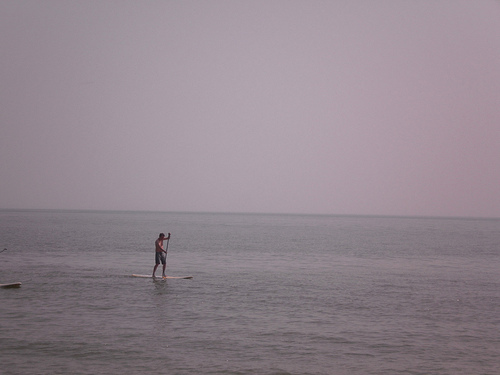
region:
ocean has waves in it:
[2, 191, 495, 373]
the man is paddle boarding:
[141, 226, 202, 296]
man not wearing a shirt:
[141, 223, 198, 293]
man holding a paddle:
[131, 211, 200, 293]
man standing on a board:
[128, 228, 195, 284]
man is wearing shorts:
[136, 242, 173, 275]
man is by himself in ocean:
[137, 220, 200, 289]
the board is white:
[122, 258, 209, 295]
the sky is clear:
[0, 1, 467, 219]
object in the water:
[2, 271, 27, 304]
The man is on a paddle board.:
[128, 228, 197, 285]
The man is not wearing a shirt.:
[131, 231, 196, 282]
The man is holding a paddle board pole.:
[133, 225, 193, 284]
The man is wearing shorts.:
[126, 227, 194, 293]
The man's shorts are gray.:
[131, 232, 193, 285]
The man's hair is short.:
[127, 230, 198, 285]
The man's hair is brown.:
[133, 233, 194, 285]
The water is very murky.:
[270, 317, 382, 368]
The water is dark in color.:
[301, 308, 375, 353]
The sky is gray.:
[316, 146, 400, 205]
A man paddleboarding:
[128, 223, 205, 292]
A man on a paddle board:
[122, 227, 202, 296]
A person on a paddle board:
[130, 231, 202, 291]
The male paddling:
[125, 221, 197, 291]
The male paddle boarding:
[125, 231, 202, 281]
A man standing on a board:
[125, 222, 208, 287]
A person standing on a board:
[130, 229, 204, 289]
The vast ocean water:
[272, 218, 499, 360]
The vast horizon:
[8, 194, 497, 239]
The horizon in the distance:
[2, 196, 497, 239]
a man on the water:
[120, 226, 234, 319]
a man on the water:
[100, 200, 193, 302]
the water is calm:
[260, 235, 365, 334]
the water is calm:
[283, 230, 358, 285]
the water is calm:
[198, 290, 286, 345]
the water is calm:
[49, 304, 204, 368]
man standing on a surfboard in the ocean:
[125, 220, 202, 292]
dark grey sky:
[139, 52, 344, 139]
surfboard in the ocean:
[124, 268, 196, 285]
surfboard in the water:
[121, 269, 195, 287]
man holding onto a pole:
[148, 228, 179, 279]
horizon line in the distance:
[276, 200, 411, 234]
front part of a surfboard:
[2, 272, 24, 293]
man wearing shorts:
[146, 228, 173, 276]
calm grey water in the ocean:
[299, 233, 421, 307]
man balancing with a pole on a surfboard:
[145, 214, 196, 286]